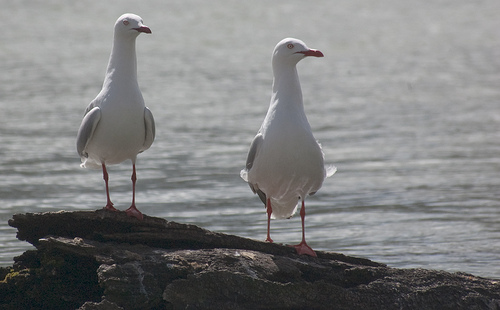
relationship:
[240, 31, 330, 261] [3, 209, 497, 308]
bird standing on rocks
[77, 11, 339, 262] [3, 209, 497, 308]
two birds are on rocks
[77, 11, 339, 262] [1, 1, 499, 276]
two birds are near water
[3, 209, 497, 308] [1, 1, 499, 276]
rocks are near water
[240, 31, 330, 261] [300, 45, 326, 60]
bird has a beak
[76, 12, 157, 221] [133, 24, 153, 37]
two birds has a beak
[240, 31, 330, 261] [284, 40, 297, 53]
bird has an eye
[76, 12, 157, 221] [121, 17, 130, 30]
two birds has an eye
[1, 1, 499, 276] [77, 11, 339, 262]
water behind two birds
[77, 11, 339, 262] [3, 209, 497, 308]
two birds are standing on top rocks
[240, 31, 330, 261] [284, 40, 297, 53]
bird has a eye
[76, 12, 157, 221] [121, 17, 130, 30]
two birds has a eye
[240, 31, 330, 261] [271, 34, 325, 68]
bird has a head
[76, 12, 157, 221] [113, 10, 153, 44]
two birds has a head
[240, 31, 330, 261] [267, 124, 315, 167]
bird has a chest